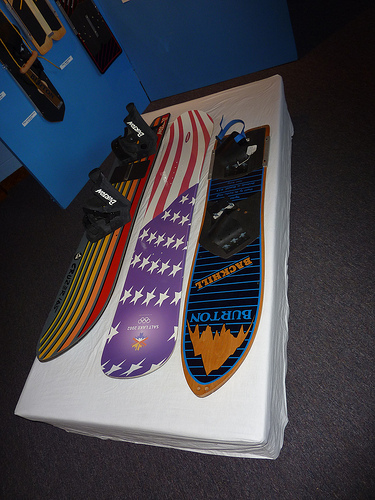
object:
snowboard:
[180, 124, 270, 399]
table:
[15, 74, 296, 462]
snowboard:
[101, 110, 215, 384]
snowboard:
[36, 110, 170, 363]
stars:
[100, 195, 197, 378]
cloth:
[13, 74, 294, 461]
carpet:
[0, 0, 374, 499]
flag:
[100, 109, 215, 381]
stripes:
[142, 109, 213, 228]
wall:
[0, 1, 299, 209]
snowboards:
[2, 2, 123, 128]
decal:
[186, 315, 256, 374]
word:
[196, 255, 252, 293]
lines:
[36, 113, 170, 364]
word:
[96, 189, 116, 208]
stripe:
[38, 116, 163, 362]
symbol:
[127, 314, 160, 332]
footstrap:
[216, 116, 251, 148]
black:
[81, 168, 132, 242]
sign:
[59, 56, 74, 70]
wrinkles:
[205, 94, 259, 116]